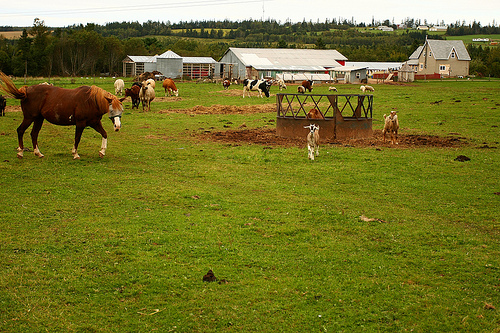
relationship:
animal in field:
[358, 106, 413, 158] [3, 80, 495, 328]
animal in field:
[296, 117, 335, 159] [3, 80, 495, 328]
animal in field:
[3, 75, 123, 162] [3, 80, 495, 328]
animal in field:
[239, 69, 279, 112] [3, 80, 495, 328]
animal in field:
[159, 76, 181, 98] [3, 80, 495, 328]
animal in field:
[126, 82, 143, 112] [3, 80, 495, 328]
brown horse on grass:
[3, 78, 129, 164] [12, 157, 122, 169]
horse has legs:
[5, 61, 150, 164] [70, 109, 113, 161]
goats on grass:
[294, 120, 329, 169] [2, 78, 497, 330]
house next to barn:
[396, 40, 471, 77] [219, 47, 347, 78]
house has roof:
[396, 40, 471, 77] [426, 37, 471, 61]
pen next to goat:
[268, 87, 378, 140] [300, 122, 324, 162]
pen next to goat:
[268, 87, 378, 140] [375, 106, 406, 148]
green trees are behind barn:
[2, 21, 494, 76] [117, 36, 401, 82]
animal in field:
[358, 106, 413, 158] [100, 197, 360, 287]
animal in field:
[134, 77, 156, 112] [3, 80, 495, 328]